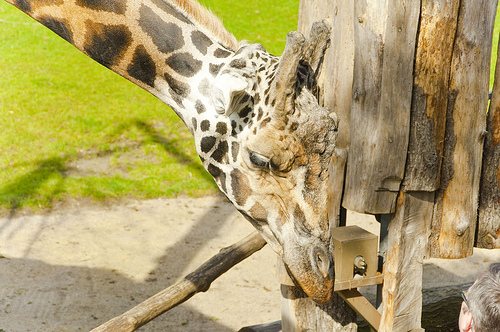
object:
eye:
[244, 146, 271, 173]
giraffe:
[0, 0, 339, 304]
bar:
[341, 0, 423, 217]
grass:
[0, 0, 299, 220]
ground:
[0, 0, 324, 332]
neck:
[4, 0, 221, 88]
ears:
[208, 69, 259, 114]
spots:
[200, 135, 219, 153]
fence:
[264, 0, 500, 331]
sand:
[0, 199, 288, 332]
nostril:
[311, 250, 330, 277]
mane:
[160, 0, 236, 47]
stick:
[87, 234, 267, 332]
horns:
[292, 21, 333, 84]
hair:
[463, 262, 500, 331]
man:
[445, 258, 500, 332]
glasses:
[453, 287, 472, 312]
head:
[202, 22, 356, 308]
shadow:
[0, 254, 225, 332]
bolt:
[354, 255, 368, 275]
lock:
[326, 225, 383, 293]